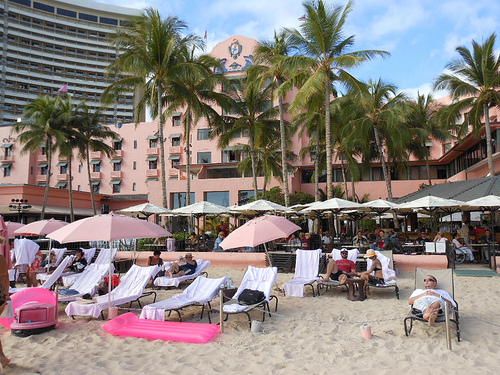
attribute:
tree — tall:
[61, 98, 121, 218]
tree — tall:
[100, 6, 234, 231]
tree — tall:
[154, 41, 245, 241]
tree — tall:
[252, 2, 396, 237]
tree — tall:
[96, 0, 213, 213]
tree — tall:
[10, 82, 99, 222]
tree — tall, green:
[433, 30, 498, 180]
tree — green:
[333, 77, 413, 204]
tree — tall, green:
[271, 0, 393, 201]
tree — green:
[201, 58, 302, 207]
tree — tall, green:
[10, 85, 85, 220]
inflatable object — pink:
[105, 312, 220, 344]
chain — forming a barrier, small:
[106, 303, 144, 314]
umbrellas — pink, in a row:
[5, 204, 307, 251]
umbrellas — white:
[121, 195, 498, 220]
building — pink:
[3, 33, 497, 204]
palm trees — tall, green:
[9, 0, 498, 219]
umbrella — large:
[216, 214, 304, 294]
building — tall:
[1, 1, 148, 127]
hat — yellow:
[362, 246, 378, 261]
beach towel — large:
[283, 244, 322, 299]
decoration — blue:
[215, 54, 254, 74]